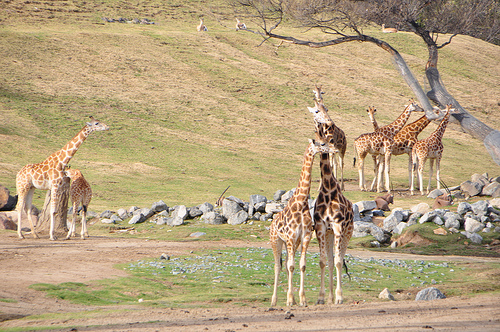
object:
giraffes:
[269, 131, 339, 306]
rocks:
[227, 209, 249, 225]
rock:
[414, 287, 446, 300]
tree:
[205, 0, 500, 155]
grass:
[142, 244, 442, 303]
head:
[86, 115, 110, 131]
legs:
[16, 181, 31, 239]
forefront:
[0, 224, 500, 332]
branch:
[239, 2, 266, 34]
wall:
[105, 196, 500, 235]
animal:
[196, 18, 208, 32]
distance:
[0, 0, 500, 43]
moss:
[363, 217, 500, 255]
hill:
[0, 0, 500, 174]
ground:
[0, 214, 500, 332]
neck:
[40, 125, 93, 170]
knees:
[50, 209, 57, 217]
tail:
[82, 186, 88, 213]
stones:
[168, 204, 188, 228]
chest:
[286, 213, 312, 238]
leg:
[49, 187, 62, 241]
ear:
[86, 121, 92, 126]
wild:
[0, 0, 500, 332]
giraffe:
[14, 114, 108, 241]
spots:
[324, 177, 330, 188]